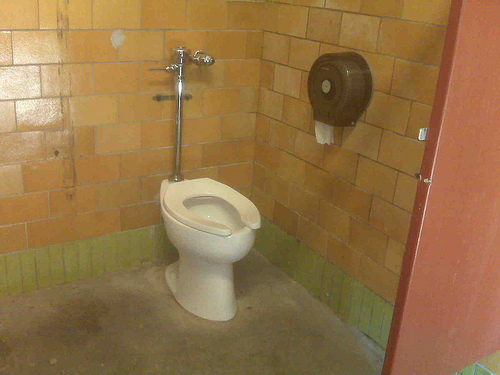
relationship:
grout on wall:
[7, 6, 444, 347] [3, 6, 428, 368]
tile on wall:
[1, 2, 459, 351] [1, 3, 142, 223]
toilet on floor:
[160, 173, 262, 322] [0, 302, 185, 372]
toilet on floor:
[160, 177, 262, 322] [0, 320, 345, 368]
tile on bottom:
[1, 2, 155, 262] [251, 219, 393, 347]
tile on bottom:
[1, 2, 155, 262] [4, 220, 221, 302]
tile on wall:
[1, 2, 155, 262] [4, 1, 256, 201]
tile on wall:
[1, 2, 155, 262] [257, 0, 451, 310]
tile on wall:
[1, 2, 459, 351] [3, 6, 428, 368]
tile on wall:
[1, 2, 155, 262] [2, 0, 148, 262]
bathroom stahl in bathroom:
[389, 0, 483, 372] [0, 1, 386, 372]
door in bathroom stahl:
[415, 42, 482, 359] [389, 0, 483, 372]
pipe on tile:
[151, 57, 208, 179] [1, 2, 459, 351]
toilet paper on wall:
[291, 40, 381, 147] [209, 32, 487, 284]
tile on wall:
[1, 2, 459, 351] [243, 124, 424, 284]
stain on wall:
[34, 296, 143, 353] [151, 38, 433, 298]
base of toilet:
[162, 251, 237, 321] [160, 173, 262, 322]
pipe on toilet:
[147, 46, 215, 183] [132, 135, 340, 364]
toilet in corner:
[160, 173, 262, 322] [176, 21, 319, 292]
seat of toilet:
[163, 176, 260, 236] [145, 96, 276, 312]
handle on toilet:
[144, 60, 176, 77] [142, 163, 271, 325]